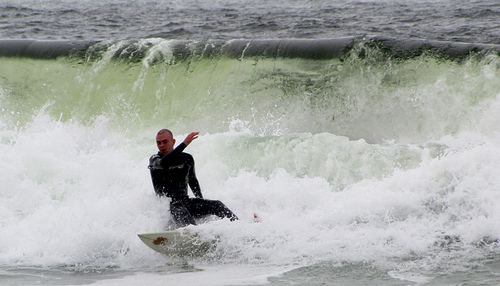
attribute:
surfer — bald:
[147, 129, 240, 227]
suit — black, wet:
[146, 152, 240, 226]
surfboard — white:
[135, 231, 217, 256]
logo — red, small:
[153, 236, 169, 248]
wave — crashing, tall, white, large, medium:
[1, 39, 497, 265]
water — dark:
[1, 1, 499, 45]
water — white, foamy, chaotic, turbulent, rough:
[0, 255, 498, 284]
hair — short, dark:
[157, 129, 174, 140]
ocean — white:
[1, 2, 498, 283]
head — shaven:
[156, 128, 176, 152]